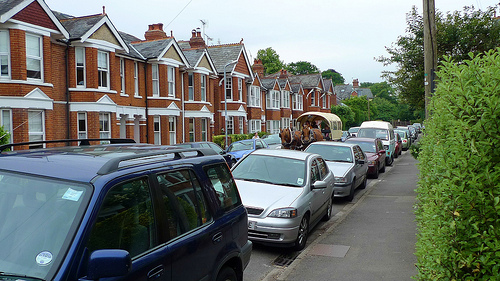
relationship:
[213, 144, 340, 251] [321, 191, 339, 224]
car has tire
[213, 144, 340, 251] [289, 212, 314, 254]
car has tire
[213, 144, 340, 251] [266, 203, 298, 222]
car has headlight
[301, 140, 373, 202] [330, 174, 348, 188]
car has headlight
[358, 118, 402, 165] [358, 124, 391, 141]
van has windshield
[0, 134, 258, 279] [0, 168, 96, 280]
van has windshield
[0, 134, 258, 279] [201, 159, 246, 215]
van has window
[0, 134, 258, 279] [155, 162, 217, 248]
van has window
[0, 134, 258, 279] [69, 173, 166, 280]
van has window